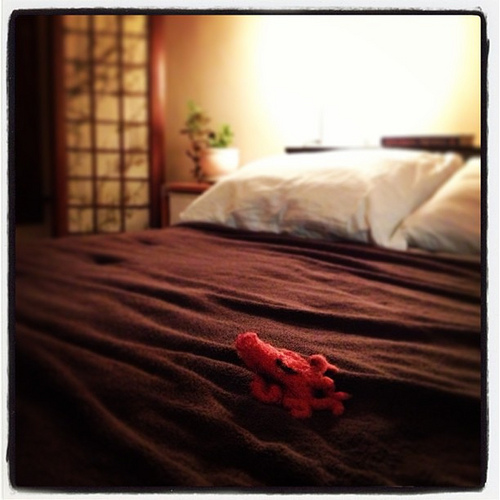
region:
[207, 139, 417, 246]
a white pillow on the bed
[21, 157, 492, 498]
a bed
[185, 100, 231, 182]
a flower in a vase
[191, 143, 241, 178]
a white flower pot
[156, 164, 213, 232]
an end table next to the bed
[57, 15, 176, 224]
the door to the room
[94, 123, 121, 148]
a window on the door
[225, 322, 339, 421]
a red stuffed animal on the bed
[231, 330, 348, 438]
red soft item on bed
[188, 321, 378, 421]
red squid looking item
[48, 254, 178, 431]
soft brown looking blanket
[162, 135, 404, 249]
big white fluffy pillow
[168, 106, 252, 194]
plant in a white jar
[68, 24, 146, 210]
japanese looking door/window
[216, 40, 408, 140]
bright reflection from light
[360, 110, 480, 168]
a closed book behind bed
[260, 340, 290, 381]
black object on red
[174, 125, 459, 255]
white pillow on the bed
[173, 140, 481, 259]
two pillows propped up on the bed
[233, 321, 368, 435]
object laying on the bed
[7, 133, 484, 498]
bed is made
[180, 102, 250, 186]
small green plant in a white pot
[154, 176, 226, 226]
table next to the bed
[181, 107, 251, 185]
plant on the table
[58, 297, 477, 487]
wrinkles in the covers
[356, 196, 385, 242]
wrinkle on the pollow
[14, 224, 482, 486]
dark covers on the bed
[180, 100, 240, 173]
A plant is on the nightstand.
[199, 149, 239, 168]
The pot is white.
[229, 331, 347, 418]
A toy is on the bed.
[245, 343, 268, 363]
The toy is red.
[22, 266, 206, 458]
The sheet is brown.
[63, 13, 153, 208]
A screen is in the background.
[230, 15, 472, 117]
A light illuminates the wall.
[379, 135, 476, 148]
A book is on the bed.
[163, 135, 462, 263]
white pillow on the bed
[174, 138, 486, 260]
two white pillows propped up on the bed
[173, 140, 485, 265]
pillows laying next to each other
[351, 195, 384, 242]
wrinkle on the pillow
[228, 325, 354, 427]
object on the bed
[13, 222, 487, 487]
dark covers on the bed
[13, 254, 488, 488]
wrinkles on the covers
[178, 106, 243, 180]
small green plant in a white pot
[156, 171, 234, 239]
small table beside the bed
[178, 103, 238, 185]
plant on the table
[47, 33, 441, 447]
this is a bedroom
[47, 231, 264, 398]
the blanket is brown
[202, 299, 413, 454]
the animal is a frog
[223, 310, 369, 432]
the frog is red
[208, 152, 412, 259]
the pillows are white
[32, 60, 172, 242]
this is a paper barrier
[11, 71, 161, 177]
the barrier is white and brown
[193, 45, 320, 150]
the wall is lit up